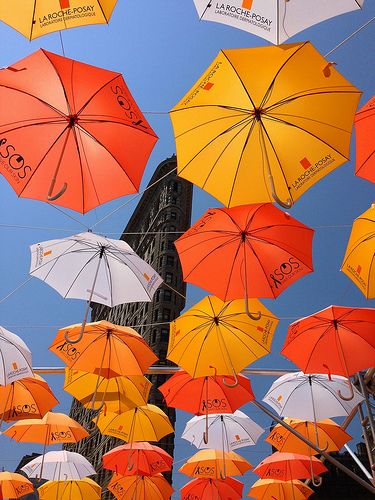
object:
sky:
[277, 196, 367, 311]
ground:
[264, 134, 272, 155]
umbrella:
[106, 470, 174, 499]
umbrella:
[178, 449, 255, 500]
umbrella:
[0, 47, 158, 215]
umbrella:
[0, 373, 60, 429]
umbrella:
[101, 441, 173, 499]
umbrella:
[20, 449, 96, 500]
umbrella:
[166, 295, 281, 389]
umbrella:
[261, 371, 367, 452]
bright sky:
[119, 3, 193, 71]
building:
[62, 153, 194, 500]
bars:
[203, 377, 208, 445]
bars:
[35, 426, 48, 483]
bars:
[127, 409, 137, 472]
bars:
[309, 378, 329, 453]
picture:
[0, 0, 375, 500]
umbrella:
[0, 0, 116, 42]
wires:
[323, 17, 375, 58]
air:
[2, 1, 371, 499]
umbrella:
[48, 320, 160, 411]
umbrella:
[340, 201, 375, 301]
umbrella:
[63, 365, 153, 431]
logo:
[299, 157, 311, 170]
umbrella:
[168, 40, 362, 209]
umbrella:
[354, 94, 375, 184]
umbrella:
[36, 477, 100, 500]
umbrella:
[174, 202, 315, 320]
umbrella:
[28, 231, 164, 343]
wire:
[91, 167, 176, 228]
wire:
[104, 232, 185, 235]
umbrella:
[0, 325, 35, 388]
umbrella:
[0, 470, 33, 500]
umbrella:
[179, 475, 243, 498]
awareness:
[270, 257, 299, 288]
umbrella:
[252, 451, 328, 500]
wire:
[0, 276, 34, 303]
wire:
[0, 316, 302, 328]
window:
[163, 308, 170, 322]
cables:
[0, 0, 375, 500]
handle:
[245, 293, 261, 320]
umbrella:
[280, 304, 374, 401]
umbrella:
[157, 368, 255, 445]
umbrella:
[192, 0, 366, 47]